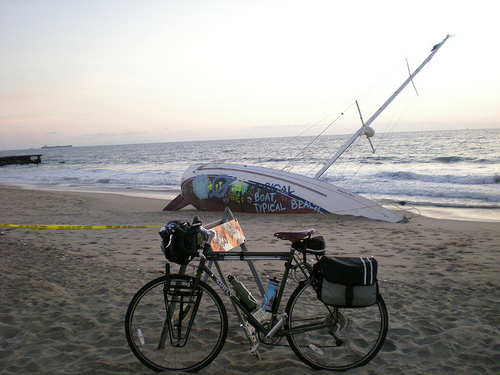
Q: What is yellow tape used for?
A: A crime scene.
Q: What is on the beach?
A: A sailboat.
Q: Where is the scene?
A: A seashore.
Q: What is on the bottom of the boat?
A: Graffiti.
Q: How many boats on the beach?
A: 1.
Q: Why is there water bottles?
A: Quenches thirst.